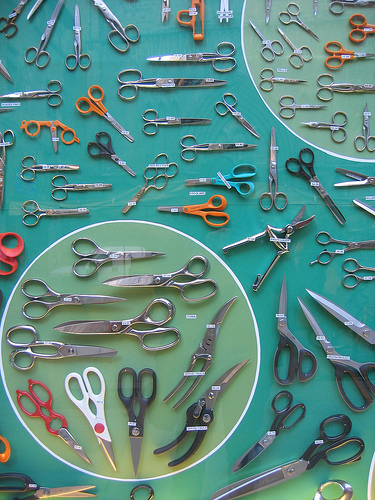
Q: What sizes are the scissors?
A: Large and small.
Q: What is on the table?
A: Scissors.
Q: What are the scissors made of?
A: Metal.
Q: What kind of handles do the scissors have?
A: Different ones.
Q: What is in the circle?
A: Scissors.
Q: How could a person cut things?
A: Scissors.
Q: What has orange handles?
A: Some of the scissors.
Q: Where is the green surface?
A: Under scissors.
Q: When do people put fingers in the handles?
A: When using scissors.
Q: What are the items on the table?
A: Scissors and pliers.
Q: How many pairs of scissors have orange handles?
A: Seven.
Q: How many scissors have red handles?
A: One.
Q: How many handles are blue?
A: One.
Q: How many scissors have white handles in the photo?
A: One.